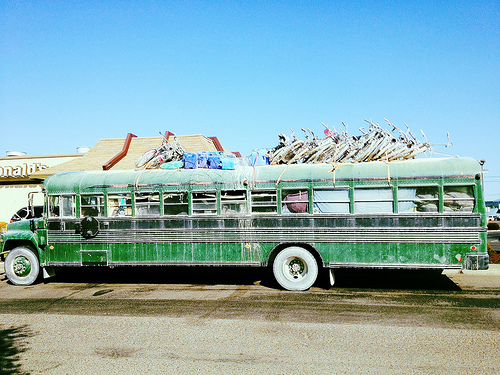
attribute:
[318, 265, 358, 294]
flap — white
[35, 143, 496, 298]
bus — full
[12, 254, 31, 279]
rim — green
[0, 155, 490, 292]
bus — green, school, old, very dirty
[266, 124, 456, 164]
bikes — several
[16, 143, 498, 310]
bus — green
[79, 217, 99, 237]
sign — closed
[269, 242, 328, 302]
tire — old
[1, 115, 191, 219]
restaurant — McDonald's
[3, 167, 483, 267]
greenpaint — green, worn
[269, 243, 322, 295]
tire — white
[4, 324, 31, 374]
shadow — cast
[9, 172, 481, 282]
bus — old, green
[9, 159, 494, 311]
bus — dilapidated, green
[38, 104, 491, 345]
bus — old, green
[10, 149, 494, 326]
bus — green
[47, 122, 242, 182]
building — McDonald's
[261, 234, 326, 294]
tire — deflated, work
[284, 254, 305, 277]
center — green